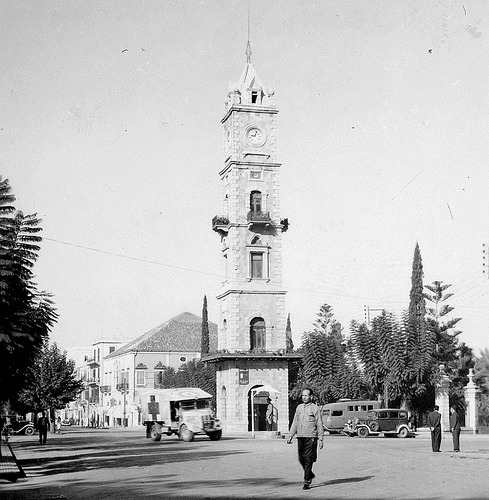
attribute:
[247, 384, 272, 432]
doorway — arched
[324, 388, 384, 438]
train — red, black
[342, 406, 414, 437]
car — old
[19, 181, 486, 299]
clouds — white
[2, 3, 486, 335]
sky — blue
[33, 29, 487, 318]
sky — blue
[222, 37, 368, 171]
clouds — white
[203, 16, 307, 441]
tower — clock